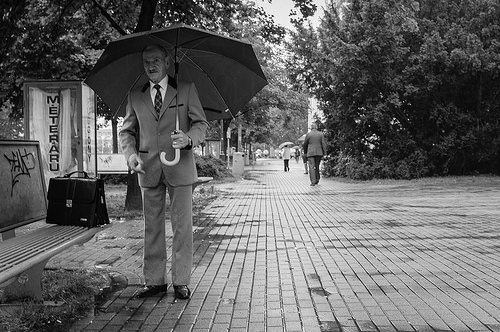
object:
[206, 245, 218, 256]
brick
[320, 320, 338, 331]
brick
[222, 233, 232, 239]
brick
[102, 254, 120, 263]
brick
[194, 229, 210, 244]
brick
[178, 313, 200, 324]
brick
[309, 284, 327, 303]
wet brick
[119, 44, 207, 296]
person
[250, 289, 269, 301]
wet brick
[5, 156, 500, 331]
sidewalk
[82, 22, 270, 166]
umbrella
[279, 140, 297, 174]
person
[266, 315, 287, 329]
brick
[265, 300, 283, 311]
brick